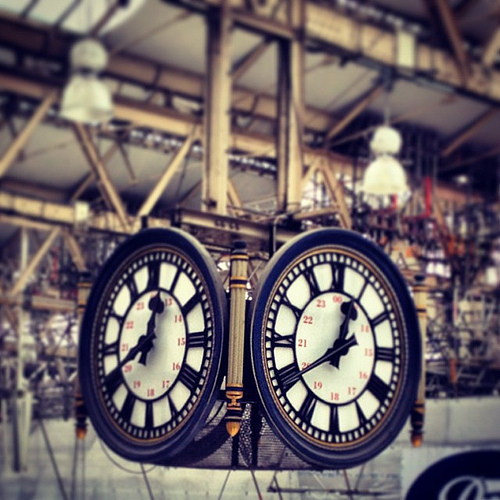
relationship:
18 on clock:
[328, 387, 342, 405] [244, 226, 425, 474]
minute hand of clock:
[288, 337, 359, 396] [244, 226, 425, 474]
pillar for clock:
[223, 230, 251, 359] [244, 226, 425, 474]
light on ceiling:
[58, 27, 128, 132] [77, 13, 313, 112]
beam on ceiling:
[202, 14, 244, 183] [77, 13, 313, 112]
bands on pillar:
[284, 14, 307, 55] [223, 230, 251, 359]